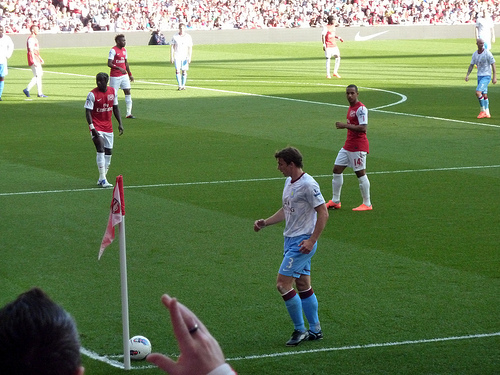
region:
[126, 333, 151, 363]
Soccer ball with logos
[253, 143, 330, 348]
Man in a blue and white soccer uniform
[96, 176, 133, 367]
Red and white flag in the corner of the soccer field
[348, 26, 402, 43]
Nike logo on a wall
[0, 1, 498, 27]
Crowd of fans at a soccer game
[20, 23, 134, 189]
Three men in red and white soccer uniforms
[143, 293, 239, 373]
Man's hand with a metal ring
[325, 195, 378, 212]
Pair of orange soccer cleats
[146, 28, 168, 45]
Cameraman filming a soccer game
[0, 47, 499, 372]
Green soccer field with white lines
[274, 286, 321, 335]
A pair of blue socks.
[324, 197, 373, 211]
A pair of orange shoes.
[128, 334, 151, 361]
A soccer ball.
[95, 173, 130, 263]
A red flag.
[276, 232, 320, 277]
A pair of blue pants.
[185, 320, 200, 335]
A ring.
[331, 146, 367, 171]
A pair of white pants.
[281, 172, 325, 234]
A white shirts.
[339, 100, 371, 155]
A red and white shirts.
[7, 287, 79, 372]
Back of a head.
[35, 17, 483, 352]
men playing soccer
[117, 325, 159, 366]
white soccer ball in corner of field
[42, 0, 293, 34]
spectators sitting in the stands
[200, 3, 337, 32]
spectators watching soccer game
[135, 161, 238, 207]
white lines drawing boundarieson soccer field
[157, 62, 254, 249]
green soccer field manicured with stripes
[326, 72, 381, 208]
red and white soccer uniform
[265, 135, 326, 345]
blue and white soccer uniform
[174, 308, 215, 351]
ring on man's hand in the foreground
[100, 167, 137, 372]
red and white flag and pole in the corner of the field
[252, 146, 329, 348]
a soccer player on field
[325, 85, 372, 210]
a soccer player on field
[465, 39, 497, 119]
a soccer player on field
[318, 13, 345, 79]
a soccer player on field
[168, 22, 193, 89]
a soccer player on field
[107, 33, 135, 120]
a soccer player on field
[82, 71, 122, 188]
a soccer player on field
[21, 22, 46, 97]
a soccer player on field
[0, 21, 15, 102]
a soccer player on field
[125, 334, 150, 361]
a white soccer ball on field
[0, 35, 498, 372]
The grass is green.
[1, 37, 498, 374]
The grass is short.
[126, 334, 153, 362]
The ball is white.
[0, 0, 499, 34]
People are in the stands.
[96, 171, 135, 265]
A flag.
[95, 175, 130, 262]
The flag is red and white.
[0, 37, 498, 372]
Lines are on the grass.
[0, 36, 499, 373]
The lines are white.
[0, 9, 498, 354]
The people are playing soccer.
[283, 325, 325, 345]
The person is wearing black shoes.